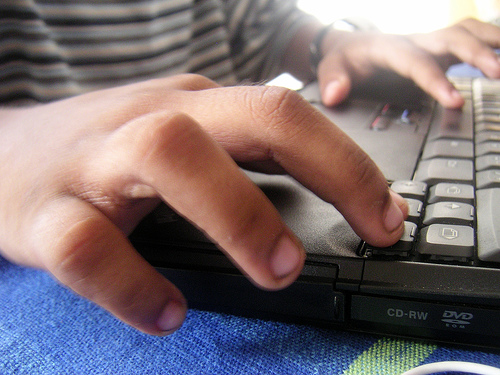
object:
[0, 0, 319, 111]
black shirt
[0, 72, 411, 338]
hands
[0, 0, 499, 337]
person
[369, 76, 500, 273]
ground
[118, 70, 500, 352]
laptop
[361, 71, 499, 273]
keyboard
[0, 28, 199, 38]
blue lines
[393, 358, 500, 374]
cord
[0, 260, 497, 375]
table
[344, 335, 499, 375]
mat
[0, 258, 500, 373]
tablecloth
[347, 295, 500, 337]
optical drive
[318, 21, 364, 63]
wrist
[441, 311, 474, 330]
logo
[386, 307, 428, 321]
lettering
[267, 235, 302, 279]
nails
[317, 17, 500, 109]
hand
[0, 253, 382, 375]
blue jeans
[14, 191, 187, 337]
finger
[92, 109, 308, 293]
finger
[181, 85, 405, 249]
finger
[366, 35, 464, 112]
finger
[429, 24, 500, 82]
finger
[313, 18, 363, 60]
watch